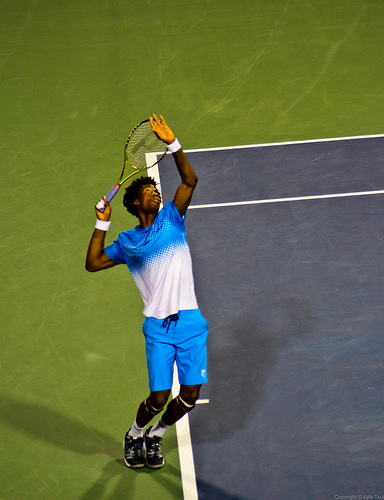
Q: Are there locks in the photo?
A: No, there are no locks.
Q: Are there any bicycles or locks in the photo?
A: No, there are no locks or bicycles.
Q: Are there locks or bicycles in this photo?
A: No, there are no locks or bicycles.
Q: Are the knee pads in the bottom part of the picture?
A: Yes, the knee pads are in the bottom of the image.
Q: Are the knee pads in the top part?
A: No, the knee pads are in the bottom of the image.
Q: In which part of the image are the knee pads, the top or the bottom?
A: The knee pads are in the bottom of the image.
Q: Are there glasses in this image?
A: No, there are no glasses.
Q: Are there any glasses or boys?
A: No, there are no glasses or boys.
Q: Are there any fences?
A: No, there are no fences.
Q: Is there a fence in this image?
A: No, there are no fences.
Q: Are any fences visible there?
A: No, there are no fences.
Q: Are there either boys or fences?
A: No, there are no fences or boys.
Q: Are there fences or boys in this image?
A: No, there are no fences or boys.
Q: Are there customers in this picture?
A: No, there are no customers.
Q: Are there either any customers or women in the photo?
A: No, there are no customers or women.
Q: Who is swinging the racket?
A: The man is swinging the racket.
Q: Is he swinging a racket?
A: Yes, the man is swinging a racket.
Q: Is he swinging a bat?
A: No, the man is swinging a racket.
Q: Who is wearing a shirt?
A: The man is wearing a shirt.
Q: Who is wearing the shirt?
A: The man is wearing a shirt.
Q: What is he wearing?
A: The man is wearing a shirt.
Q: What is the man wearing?
A: The man is wearing a shirt.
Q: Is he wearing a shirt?
A: Yes, the man is wearing a shirt.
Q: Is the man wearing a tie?
A: No, the man is wearing a shirt.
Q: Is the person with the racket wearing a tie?
A: No, the man is wearing a shirt.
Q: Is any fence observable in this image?
A: No, there are no fences.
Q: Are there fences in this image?
A: No, there are no fences.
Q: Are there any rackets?
A: Yes, there is a racket.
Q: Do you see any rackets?
A: Yes, there is a racket.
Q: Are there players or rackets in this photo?
A: Yes, there is a racket.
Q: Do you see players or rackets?
A: Yes, there is a racket.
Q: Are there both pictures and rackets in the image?
A: No, there is a racket but no pictures.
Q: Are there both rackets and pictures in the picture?
A: No, there is a racket but no pictures.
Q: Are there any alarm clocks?
A: No, there are no alarm clocks.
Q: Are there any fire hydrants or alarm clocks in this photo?
A: No, there are no alarm clocks or fire hydrants.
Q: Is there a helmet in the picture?
A: No, there are no helmets.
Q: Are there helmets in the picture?
A: No, there are no helmets.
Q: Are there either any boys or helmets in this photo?
A: No, there are no helmets or boys.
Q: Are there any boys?
A: No, there are no boys.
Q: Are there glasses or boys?
A: No, there are no boys or glasses.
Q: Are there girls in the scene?
A: No, there are no girls.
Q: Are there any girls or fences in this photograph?
A: No, there are no girls or fences.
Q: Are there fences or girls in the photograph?
A: No, there are no girls or fences.